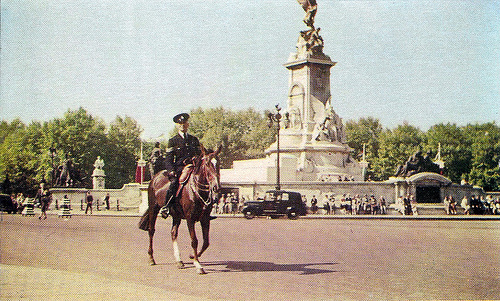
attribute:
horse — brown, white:
[144, 149, 225, 253]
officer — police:
[173, 112, 196, 161]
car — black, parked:
[242, 182, 305, 222]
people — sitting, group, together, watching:
[311, 193, 499, 218]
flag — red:
[131, 157, 145, 183]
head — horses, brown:
[202, 154, 225, 204]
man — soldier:
[162, 105, 200, 180]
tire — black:
[247, 205, 255, 219]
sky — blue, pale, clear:
[0, 6, 495, 120]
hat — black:
[171, 112, 194, 123]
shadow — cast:
[219, 254, 331, 275]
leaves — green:
[10, 123, 152, 185]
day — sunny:
[6, 6, 499, 287]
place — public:
[4, 7, 463, 287]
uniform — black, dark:
[172, 140, 196, 165]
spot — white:
[212, 156, 218, 169]